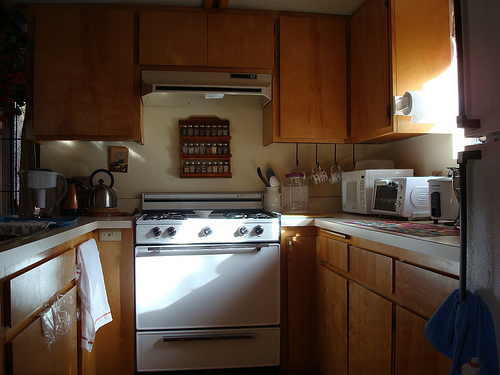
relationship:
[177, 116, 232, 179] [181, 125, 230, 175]
shelf for spices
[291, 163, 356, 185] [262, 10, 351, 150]
mugs under cabinet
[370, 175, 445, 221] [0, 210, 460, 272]
toaster oven on counter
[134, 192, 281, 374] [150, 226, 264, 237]
stove has knobs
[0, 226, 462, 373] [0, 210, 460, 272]
cabinets under counter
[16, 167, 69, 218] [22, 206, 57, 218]
pitcher for water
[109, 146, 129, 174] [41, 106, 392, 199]
picture on wall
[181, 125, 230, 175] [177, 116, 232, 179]
spices on shelf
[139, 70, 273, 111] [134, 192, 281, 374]
range over stove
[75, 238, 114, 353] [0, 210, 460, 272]
dish towel under counter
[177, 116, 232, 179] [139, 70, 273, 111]
shelf under range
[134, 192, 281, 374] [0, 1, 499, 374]
stove in kitchen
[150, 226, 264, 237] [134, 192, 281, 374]
knobs on stove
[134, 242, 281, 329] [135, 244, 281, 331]
door for oven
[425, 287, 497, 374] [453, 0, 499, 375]
towel hanging from refrigerator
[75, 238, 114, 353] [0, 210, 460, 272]
dish towel hanging under counter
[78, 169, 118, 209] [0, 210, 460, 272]
kettle on counter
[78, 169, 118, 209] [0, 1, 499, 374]
kettle in kitchen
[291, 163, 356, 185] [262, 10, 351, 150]
mugs are under cabinet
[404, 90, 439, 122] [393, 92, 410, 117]
paper towel on dispenser